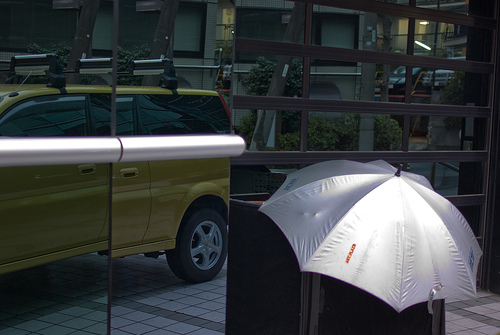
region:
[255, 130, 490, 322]
open white umbrella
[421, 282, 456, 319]
strap on side of umbrella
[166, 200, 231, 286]
tire on side of vehicle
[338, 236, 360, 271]
red label on umbrella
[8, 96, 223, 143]
window on side of vehicle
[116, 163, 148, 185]
handle on vehicle door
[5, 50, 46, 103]
antenna on front of vehicle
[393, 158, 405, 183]
pointed top of umbrella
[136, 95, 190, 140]
light reflected on window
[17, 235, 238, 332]
grey tiles cement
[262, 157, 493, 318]
A white umbrella by the building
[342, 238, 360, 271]
Small red writing on the white umbrella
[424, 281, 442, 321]
A small grey strap on the white umbrella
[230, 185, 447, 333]
A large black bin under the umbrella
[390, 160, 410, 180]
A small black cap on the white umbrella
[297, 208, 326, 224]
A small bump poking through the umbrella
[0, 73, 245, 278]
Reflection of a yellow vehicle on the building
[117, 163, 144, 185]
A small yellow handle on the car door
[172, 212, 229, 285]
A large black tire on the vehicle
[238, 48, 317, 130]
The reflection of a small green tree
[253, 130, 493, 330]
The umbrella is shiny.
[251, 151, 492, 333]
The umbrella is white.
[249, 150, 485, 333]
The umbrella is open.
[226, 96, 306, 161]
The window is rectangular.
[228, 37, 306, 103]
The window is rectangular.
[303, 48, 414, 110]
The window is rectangular.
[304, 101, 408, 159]
The window is rectangular.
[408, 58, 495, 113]
The window is rectangular.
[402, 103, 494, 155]
The window is rectangular.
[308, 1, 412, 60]
The window is rectangular.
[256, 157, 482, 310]
opened white umbrella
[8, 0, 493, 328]
building with lots of reflective surfaces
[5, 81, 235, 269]
yellow SUV in the reflection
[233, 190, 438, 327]
black valet stand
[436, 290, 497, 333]
a bricked sidewalk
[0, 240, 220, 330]
a bricked ground area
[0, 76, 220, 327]
car parked on bricked ground area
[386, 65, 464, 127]
cars parked across the street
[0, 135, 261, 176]
metal railing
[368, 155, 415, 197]
black tip on umbrella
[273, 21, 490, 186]
black frame around window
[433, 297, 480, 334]
tile is light grey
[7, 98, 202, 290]
yellow car in reflection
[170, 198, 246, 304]
black tire on car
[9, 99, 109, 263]
yellow door on car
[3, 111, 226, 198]
grey bar on door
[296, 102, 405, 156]
green bush in reflection